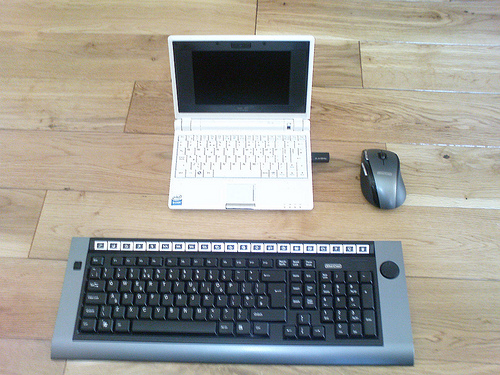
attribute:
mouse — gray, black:
[361, 143, 413, 214]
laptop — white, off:
[160, 29, 328, 235]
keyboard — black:
[58, 231, 417, 359]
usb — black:
[307, 147, 336, 168]